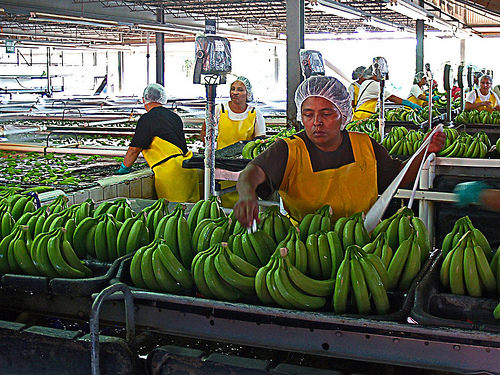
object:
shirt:
[129, 105, 188, 155]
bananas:
[226, 223, 275, 270]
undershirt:
[214, 100, 267, 138]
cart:
[0, 243, 499, 375]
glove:
[116, 162, 133, 175]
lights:
[355, 27, 368, 35]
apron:
[142, 135, 200, 205]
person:
[116, 83, 200, 203]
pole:
[203, 85, 217, 201]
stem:
[233, 226, 247, 236]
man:
[229, 74, 446, 225]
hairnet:
[294, 75, 352, 132]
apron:
[277, 131, 380, 228]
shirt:
[246, 126, 400, 200]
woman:
[200, 75, 265, 150]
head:
[229, 76, 253, 104]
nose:
[233, 90, 238, 96]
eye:
[239, 89, 244, 92]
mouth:
[233, 96, 240, 99]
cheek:
[238, 92, 246, 101]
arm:
[255, 110, 267, 139]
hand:
[233, 196, 261, 229]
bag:
[237, 76, 254, 101]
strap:
[150, 153, 186, 169]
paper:
[359, 123, 444, 234]